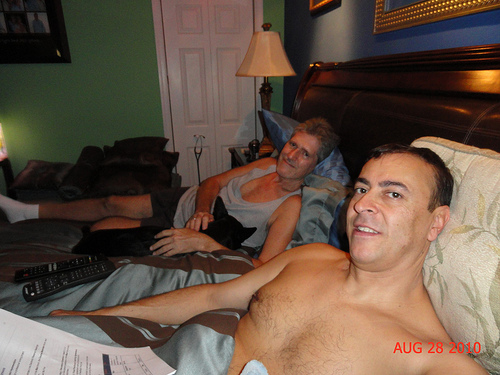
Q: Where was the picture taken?
A: It was taken at the bedroom.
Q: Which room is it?
A: It is a bedroom.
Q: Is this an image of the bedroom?
A: Yes, it is showing the bedroom.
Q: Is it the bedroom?
A: Yes, it is the bedroom.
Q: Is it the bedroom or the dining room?
A: It is the bedroom.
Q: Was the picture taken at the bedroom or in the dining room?
A: It was taken at the bedroom.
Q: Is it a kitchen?
A: No, it is a bedroom.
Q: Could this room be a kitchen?
A: No, it is a bedroom.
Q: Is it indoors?
A: Yes, it is indoors.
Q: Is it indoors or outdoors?
A: It is indoors.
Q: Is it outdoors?
A: No, it is indoors.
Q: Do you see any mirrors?
A: No, there are no mirrors.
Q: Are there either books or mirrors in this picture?
A: No, there are no mirrors or books.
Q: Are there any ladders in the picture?
A: No, there are no ladders.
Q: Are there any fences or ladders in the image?
A: No, there are no ladders or fences.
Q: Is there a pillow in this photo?
A: Yes, there is a pillow.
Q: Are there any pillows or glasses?
A: Yes, there is a pillow.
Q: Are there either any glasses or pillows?
A: Yes, there is a pillow.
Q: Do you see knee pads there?
A: No, there are no knee pads.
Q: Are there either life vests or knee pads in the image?
A: No, there are no knee pads or life vests.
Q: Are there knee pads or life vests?
A: No, there are no knee pads or life vests.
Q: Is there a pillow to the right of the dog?
A: Yes, there is a pillow to the right of the dog.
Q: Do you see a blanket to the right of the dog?
A: No, there is a pillow to the right of the dog.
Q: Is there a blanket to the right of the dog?
A: No, there is a pillow to the right of the dog.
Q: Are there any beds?
A: Yes, there is a bed.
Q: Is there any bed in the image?
A: Yes, there is a bed.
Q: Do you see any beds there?
A: Yes, there is a bed.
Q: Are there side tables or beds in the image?
A: Yes, there is a bed.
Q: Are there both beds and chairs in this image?
A: No, there is a bed but no chairs.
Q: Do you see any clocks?
A: No, there are no clocks.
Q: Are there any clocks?
A: No, there are no clocks.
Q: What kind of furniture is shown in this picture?
A: The furniture is a bed.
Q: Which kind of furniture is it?
A: The piece of furniture is a bed.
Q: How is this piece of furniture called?
A: This is a bed.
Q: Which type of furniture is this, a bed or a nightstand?
A: This is a bed.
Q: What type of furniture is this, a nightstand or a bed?
A: This is a bed.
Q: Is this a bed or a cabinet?
A: This is a bed.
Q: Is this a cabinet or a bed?
A: This is a bed.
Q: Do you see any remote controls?
A: Yes, there is a remote control.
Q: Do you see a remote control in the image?
A: Yes, there is a remote control.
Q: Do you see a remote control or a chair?
A: Yes, there is a remote control.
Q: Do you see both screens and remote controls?
A: No, there is a remote control but no screens.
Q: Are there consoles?
A: No, there are no consoles.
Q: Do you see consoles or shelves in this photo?
A: No, there are no consoles or shelves.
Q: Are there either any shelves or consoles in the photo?
A: No, there are no consoles or shelves.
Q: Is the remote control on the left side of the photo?
A: Yes, the remote control is on the left of the image.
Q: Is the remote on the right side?
A: No, the remote is on the left of the image.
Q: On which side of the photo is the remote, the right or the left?
A: The remote is on the left of the image.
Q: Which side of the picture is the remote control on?
A: The remote control is on the left of the image.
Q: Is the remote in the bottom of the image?
A: Yes, the remote is in the bottom of the image.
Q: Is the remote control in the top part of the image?
A: No, the remote control is in the bottom of the image.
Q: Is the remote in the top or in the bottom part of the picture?
A: The remote is in the bottom of the image.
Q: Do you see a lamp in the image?
A: Yes, there is a lamp.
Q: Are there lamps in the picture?
A: Yes, there is a lamp.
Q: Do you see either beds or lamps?
A: Yes, there is a lamp.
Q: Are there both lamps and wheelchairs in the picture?
A: No, there is a lamp but no wheelchairs.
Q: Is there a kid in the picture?
A: No, there are no children.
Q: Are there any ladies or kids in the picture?
A: No, there are no kids or ladies.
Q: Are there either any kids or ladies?
A: No, there are no kids or ladies.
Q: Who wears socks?
A: The man wears socks.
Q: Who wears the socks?
A: The man wears socks.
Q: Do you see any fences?
A: No, there are no fences.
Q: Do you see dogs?
A: Yes, there is a dog.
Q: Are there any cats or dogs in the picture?
A: Yes, there is a dog.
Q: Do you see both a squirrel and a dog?
A: No, there is a dog but no squirrels.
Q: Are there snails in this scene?
A: No, there are no snails.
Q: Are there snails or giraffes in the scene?
A: No, there are no snails or giraffes.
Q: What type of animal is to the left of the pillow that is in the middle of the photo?
A: The animal is a dog.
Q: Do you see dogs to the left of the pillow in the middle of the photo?
A: Yes, there is a dog to the left of the pillow.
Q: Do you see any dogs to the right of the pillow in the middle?
A: No, the dog is to the left of the pillow.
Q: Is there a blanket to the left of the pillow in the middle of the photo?
A: No, there is a dog to the left of the pillow.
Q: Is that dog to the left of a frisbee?
A: No, the dog is to the left of the pillow.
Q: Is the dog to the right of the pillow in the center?
A: No, the dog is to the left of the pillow.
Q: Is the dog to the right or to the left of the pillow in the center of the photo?
A: The dog is to the left of the pillow.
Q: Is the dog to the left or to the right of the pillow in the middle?
A: The dog is to the left of the pillow.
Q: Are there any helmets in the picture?
A: No, there are no helmets.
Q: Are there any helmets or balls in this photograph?
A: No, there are no helmets or balls.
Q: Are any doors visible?
A: Yes, there is a door.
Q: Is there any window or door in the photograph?
A: Yes, there is a door.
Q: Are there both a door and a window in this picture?
A: No, there is a door but no windows.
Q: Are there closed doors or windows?
A: Yes, there is a closed door.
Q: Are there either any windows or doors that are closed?
A: Yes, the door is closed.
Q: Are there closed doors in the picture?
A: Yes, there is a closed door.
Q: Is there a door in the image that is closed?
A: Yes, there is a door that is closed.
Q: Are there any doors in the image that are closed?
A: Yes, there is a door that is closed.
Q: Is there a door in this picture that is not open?
A: Yes, there is an closed door.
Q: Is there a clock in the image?
A: No, there are no clocks.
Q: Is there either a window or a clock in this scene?
A: No, there are no clocks or windows.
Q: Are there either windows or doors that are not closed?
A: No, there is a door but it is closed.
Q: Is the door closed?
A: Yes, the door is closed.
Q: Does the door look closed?
A: Yes, the door is closed.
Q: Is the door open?
A: No, the door is closed.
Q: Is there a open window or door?
A: No, there is a door but it is closed.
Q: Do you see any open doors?
A: No, there is a door but it is closed.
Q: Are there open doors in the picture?
A: No, there is a door but it is closed.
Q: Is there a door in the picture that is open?
A: No, there is a door but it is closed.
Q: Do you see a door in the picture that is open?
A: No, there is a door but it is closed.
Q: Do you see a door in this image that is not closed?
A: No, there is a door but it is closed.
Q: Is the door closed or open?
A: The door is closed.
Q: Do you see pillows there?
A: Yes, there is a pillow.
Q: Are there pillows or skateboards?
A: Yes, there is a pillow.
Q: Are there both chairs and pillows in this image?
A: No, there is a pillow but no chairs.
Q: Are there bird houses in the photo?
A: No, there are no bird houses.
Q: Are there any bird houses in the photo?
A: No, there are no bird houses.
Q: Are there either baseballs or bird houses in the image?
A: No, there are no bird houses or baseballs.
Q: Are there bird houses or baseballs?
A: No, there are no bird houses or baseballs.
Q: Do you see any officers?
A: No, there are no officers.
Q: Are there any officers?
A: No, there are no officers.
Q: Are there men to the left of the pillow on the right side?
A: Yes, there is a man to the left of the pillow.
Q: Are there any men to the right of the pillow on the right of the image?
A: No, the man is to the left of the pillow.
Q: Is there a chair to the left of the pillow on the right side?
A: No, there is a man to the left of the pillow.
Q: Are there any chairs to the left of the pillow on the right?
A: No, there is a man to the left of the pillow.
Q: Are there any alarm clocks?
A: No, there are no alarm clocks.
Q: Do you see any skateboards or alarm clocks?
A: No, there are no alarm clocks or skateboards.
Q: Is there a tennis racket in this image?
A: No, there are no rackets.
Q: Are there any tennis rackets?
A: No, there are no tennis rackets.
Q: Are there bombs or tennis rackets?
A: No, there are no tennis rackets or bombs.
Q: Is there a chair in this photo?
A: No, there are no chairs.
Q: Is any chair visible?
A: No, there are no chairs.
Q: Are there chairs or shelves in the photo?
A: No, there are no chairs or shelves.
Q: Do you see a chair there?
A: No, there are no chairs.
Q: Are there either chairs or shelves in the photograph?
A: No, there are no chairs or shelves.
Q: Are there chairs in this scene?
A: No, there are no chairs.